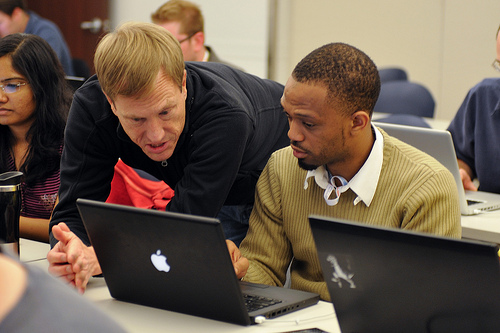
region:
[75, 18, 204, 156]
man with brown hair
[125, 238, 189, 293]
apple logo on the laptop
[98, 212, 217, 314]
black laptop with apple logo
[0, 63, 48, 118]
girl wearing pair of glasses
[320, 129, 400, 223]
collared shirt on man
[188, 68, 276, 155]
black shirt on man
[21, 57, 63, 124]
black hair of woman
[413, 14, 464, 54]
white wall in background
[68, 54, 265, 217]
man bent over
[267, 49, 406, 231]
man looking at laptop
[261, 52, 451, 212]
this is a man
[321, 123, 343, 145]
the an is light skinned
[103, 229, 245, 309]
this is a laptop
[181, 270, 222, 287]
the laptop is black in color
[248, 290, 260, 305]
these are the buttons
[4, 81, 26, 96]
this is a spectacle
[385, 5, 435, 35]
this is the wall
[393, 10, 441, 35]
the wall is white in color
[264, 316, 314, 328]
this is a cable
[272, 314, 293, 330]
the cable is white in color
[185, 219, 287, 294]
A laptop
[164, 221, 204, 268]
A laptop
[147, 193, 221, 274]
A laptop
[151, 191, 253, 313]
A laptop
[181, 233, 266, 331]
A laptop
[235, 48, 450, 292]
a man with a light green sweater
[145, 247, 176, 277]
the apple computer logo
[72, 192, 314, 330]
an apple computer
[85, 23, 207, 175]
a man leaning over a computer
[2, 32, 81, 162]
a woman in glasses looking at a computer screen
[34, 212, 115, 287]
a man's hands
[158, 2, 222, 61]
a man wearing glasses with dark rims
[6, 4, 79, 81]
a man with a blue shirt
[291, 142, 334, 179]
a beard on a man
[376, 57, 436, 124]
a couple of chairs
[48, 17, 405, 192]
two men looking at black laptop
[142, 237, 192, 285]
apple icon on laptop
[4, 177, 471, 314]
two laptops in photograph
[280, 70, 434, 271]
man wearing brown shirt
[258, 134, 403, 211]
man with a white collar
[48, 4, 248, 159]
man wearing black shirt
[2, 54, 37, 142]
woman wearing eye glasses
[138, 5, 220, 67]
man in background wearing eye glasses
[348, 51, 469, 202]
three blue chairs in background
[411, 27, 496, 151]
blue shirt on person